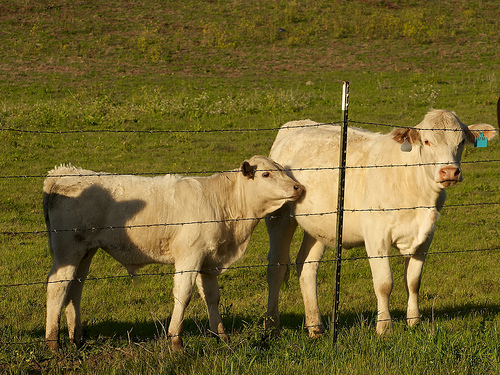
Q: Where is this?
A: This is at the field.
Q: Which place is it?
A: It is a field.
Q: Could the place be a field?
A: Yes, it is a field.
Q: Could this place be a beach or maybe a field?
A: It is a field.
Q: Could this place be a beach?
A: No, it is a field.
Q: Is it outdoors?
A: Yes, it is outdoors.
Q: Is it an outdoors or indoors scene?
A: It is outdoors.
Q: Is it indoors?
A: No, it is outdoors.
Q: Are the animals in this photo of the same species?
A: Yes, all the animals are cows.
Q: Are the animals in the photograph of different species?
A: No, all the animals are cows.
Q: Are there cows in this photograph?
A: Yes, there is a cow.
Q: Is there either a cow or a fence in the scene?
A: Yes, there is a cow.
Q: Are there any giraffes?
A: No, there are no giraffes.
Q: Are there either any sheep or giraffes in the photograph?
A: No, there are no giraffes or sheep.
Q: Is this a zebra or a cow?
A: This is a cow.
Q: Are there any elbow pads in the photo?
A: No, there are no elbow pads.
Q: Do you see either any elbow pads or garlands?
A: No, there are no elbow pads or garlands.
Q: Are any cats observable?
A: No, there are no cats.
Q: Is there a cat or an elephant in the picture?
A: No, there are no cats or elephants.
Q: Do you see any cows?
A: Yes, there is a cow.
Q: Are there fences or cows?
A: Yes, there is a cow.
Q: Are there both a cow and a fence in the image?
A: Yes, there are both a cow and a fence.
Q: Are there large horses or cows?
A: Yes, there is a large cow.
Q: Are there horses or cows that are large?
A: Yes, the cow is large.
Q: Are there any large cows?
A: Yes, there is a large cow.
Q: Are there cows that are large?
A: Yes, there is a cow that is large.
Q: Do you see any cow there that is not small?
A: Yes, there is a large cow.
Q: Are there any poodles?
A: No, there are no poodles.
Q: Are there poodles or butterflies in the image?
A: No, there are no poodles or butterflies.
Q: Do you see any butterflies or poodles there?
A: No, there are no poodles or butterflies.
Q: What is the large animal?
A: The animal is a cow.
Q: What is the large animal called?
A: The animal is a cow.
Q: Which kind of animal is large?
A: The animal is a cow.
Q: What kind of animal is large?
A: The animal is a cow.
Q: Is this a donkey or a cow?
A: This is a cow.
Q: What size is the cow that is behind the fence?
A: The cow is large.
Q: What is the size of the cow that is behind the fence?
A: The cow is large.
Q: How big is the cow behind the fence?
A: The cow is large.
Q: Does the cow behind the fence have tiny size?
A: No, the cow is large.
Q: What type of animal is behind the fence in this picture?
A: The animal is a cow.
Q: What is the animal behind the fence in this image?
A: The animal is a cow.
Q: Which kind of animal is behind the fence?
A: The animal is a cow.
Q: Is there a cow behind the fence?
A: Yes, there is a cow behind the fence.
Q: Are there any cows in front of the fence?
A: No, the cow is behind the fence.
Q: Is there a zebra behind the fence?
A: No, there is a cow behind the fence.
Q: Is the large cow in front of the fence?
A: No, the cow is behind the fence.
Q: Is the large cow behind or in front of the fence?
A: The cow is behind the fence.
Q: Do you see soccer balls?
A: No, there are no soccer balls.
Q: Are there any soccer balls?
A: No, there are no soccer balls.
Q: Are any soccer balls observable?
A: No, there are no soccer balls.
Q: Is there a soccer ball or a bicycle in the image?
A: No, there are no soccer balls or bicycles.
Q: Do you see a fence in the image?
A: Yes, there is a fence.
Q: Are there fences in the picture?
A: Yes, there is a fence.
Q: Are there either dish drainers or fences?
A: Yes, there is a fence.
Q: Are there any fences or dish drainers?
A: Yes, there is a fence.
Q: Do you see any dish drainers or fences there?
A: Yes, there is a fence.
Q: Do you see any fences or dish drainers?
A: Yes, there is a fence.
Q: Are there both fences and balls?
A: No, there is a fence but no balls.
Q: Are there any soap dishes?
A: No, there are no soap dishes.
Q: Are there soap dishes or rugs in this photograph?
A: No, there are no soap dishes or rugs.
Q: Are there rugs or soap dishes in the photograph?
A: No, there are no soap dishes or rugs.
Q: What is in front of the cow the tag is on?
A: The fence is in front of the cow.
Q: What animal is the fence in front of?
A: The fence is in front of the cow.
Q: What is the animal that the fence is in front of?
A: The animal is a cow.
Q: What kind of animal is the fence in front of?
A: The fence is in front of the cow.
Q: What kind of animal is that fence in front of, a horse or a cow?
A: The fence is in front of a cow.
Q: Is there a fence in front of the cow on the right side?
A: Yes, there is a fence in front of the cow.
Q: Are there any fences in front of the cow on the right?
A: Yes, there is a fence in front of the cow.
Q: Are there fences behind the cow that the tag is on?
A: No, the fence is in front of the cow.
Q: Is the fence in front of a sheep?
A: No, the fence is in front of the cow.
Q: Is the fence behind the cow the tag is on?
A: No, the fence is in front of the cow.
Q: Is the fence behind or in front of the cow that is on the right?
A: The fence is in front of the cow.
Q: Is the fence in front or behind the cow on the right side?
A: The fence is in front of the cow.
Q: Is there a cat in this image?
A: No, there are no cats.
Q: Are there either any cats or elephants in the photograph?
A: No, there are no cats or elephants.